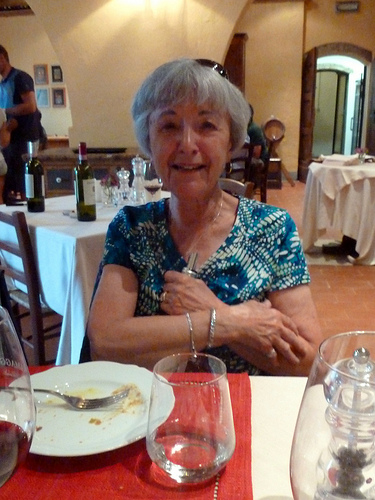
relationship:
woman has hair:
[86, 47, 335, 392] [122, 50, 253, 162]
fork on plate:
[3, 380, 134, 411] [0, 359, 176, 457]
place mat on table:
[165, 371, 252, 497] [254, 373, 374, 495]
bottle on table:
[68, 141, 100, 224] [0, 190, 166, 353]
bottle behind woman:
[68, 141, 100, 224] [78, 58, 324, 370]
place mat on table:
[0, 362, 252, 497] [9, 357, 369, 493]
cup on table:
[145, 348, 238, 485] [9, 357, 369, 493]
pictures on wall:
[33, 65, 64, 109] [77, 28, 109, 96]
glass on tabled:
[4, 363, 366, 499] [252, 380, 288, 438]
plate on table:
[0, 359, 176, 457] [9, 357, 369, 493]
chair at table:
[2, 212, 46, 365] [0, 154, 167, 239]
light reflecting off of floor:
[326, 278, 332, 290] [3, 167, 374, 373]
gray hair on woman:
[122, 51, 239, 119] [78, 58, 324, 370]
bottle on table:
[72, 141, 97, 221] [300, 146, 373, 261]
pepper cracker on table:
[313, 346, 374, 499] [0, 364, 374, 498]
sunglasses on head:
[194, 58, 228, 82] [131, 59, 250, 196]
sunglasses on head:
[186, 54, 231, 81] [111, 51, 257, 198]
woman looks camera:
[86, 47, 335, 392] [3, 3, 372, 496]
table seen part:
[297, 149, 372, 270] [324, 168, 333, 180]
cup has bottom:
[133, 348, 263, 497] [163, 470, 218, 491]